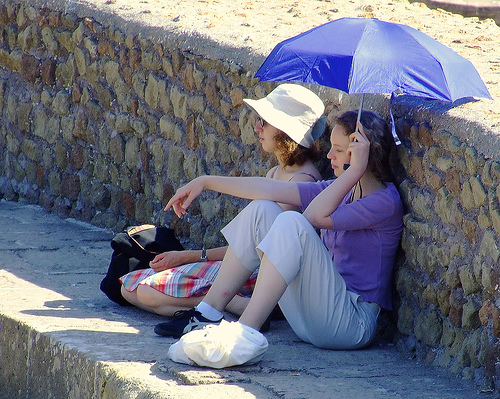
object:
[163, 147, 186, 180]
brick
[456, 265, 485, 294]
brick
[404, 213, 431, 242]
brick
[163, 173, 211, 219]
hand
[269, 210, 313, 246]
knee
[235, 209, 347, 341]
leg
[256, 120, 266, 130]
nose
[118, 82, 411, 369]
two girls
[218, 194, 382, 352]
tan pants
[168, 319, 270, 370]
package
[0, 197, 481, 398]
sidewalk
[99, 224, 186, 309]
back pack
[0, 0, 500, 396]
wall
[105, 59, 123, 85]
stones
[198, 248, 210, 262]
watch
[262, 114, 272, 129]
eyeglasses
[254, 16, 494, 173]
umbrella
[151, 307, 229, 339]
shoe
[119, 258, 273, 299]
skirt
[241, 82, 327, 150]
hat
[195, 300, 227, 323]
sock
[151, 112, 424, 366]
girl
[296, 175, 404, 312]
shirt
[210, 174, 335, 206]
right arm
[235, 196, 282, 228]
right knee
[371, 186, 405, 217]
left shoulder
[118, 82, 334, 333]
woman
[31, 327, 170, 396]
shadows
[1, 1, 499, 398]
scene